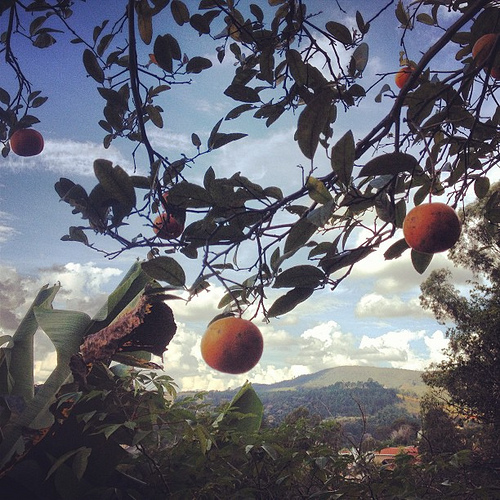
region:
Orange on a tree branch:
[206, 295, 261, 361]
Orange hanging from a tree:
[361, 150, 456, 267]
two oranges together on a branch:
[140, 180, 199, 269]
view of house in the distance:
[353, 420, 435, 488]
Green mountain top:
[285, 355, 403, 422]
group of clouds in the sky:
[352, 285, 432, 372]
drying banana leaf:
[78, 300, 173, 385]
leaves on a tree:
[203, 15, 365, 154]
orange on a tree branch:
[16, 115, 71, 190]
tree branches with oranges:
[307, 124, 439, 274]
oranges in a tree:
[201, 291, 278, 374]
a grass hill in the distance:
[264, 363, 415, 405]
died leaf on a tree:
[68, 283, 149, 420]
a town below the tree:
[331, 422, 426, 489]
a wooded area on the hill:
[321, 372, 420, 417]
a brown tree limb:
[231, 143, 352, 246]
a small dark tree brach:
[132, 181, 164, 216]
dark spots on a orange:
[404, 197, 460, 267]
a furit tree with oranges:
[28, 23, 491, 410]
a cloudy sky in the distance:
[301, 293, 422, 371]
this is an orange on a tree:
[139, 237, 296, 389]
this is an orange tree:
[53, 35, 492, 377]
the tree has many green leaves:
[131, 61, 373, 251]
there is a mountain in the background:
[283, 353, 408, 407]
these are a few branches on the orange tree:
[206, 25, 467, 323]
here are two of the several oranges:
[185, 194, 464, 390]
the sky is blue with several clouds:
[48, 128, 383, 365]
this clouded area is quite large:
[133, 299, 416, 379]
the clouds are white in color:
[290, 326, 403, 365]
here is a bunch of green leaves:
[64, 394, 334, 495]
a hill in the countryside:
[152, 347, 473, 459]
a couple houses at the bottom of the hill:
[337, 435, 434, 472]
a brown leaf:
[71, 301, 173, 358]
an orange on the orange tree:
[198, 313, 266, 378]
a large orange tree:
[1, 6, 492, 383]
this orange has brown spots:
[395, 201, 468, 254]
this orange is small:
[392, 64, 423, 91]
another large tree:
[407, 174, 497, 496]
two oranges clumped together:
[146, 187, 185, 244]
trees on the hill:
[182, 367, 400, 446]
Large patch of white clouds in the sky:
[311, 326, 415, 368]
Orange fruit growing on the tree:
[192, 312, 263, 373]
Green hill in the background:
[343, 364, 380, 381]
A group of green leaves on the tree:
[201, 178, 257, 223]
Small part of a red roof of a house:
[383, 448, 400, 453]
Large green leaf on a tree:
[47, 295, 77, 433]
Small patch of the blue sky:
[27, 193, 43, 213]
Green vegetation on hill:
[331, 390, 348, 405]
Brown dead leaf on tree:
[96, 306, 161, 352]